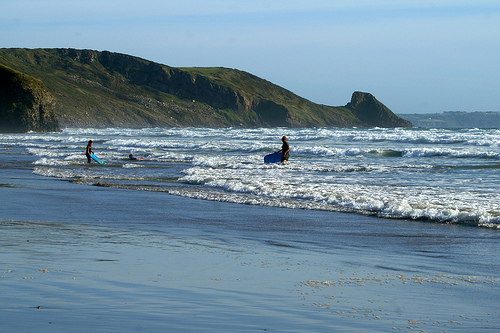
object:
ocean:
[1, 129, 500, 332]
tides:
[175, 165, 298, 201]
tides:
[351, 187, 495, 221]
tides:
[365, 147, 440, 161]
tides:
[364, 130, 449, 142]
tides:
[293, 127, 333, 139]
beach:
[2, 136, 499, 333]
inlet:
[0, 0, 500, 332]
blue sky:
[2, 0, 497, 112]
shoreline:
[0, 154, 500, 333]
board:
[264, 151, 288, 164]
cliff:
[0, 48, 413, 129]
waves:
[0, 127, 500, 231]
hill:
[0, 48, 426, 130]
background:
[0, 47, 499, 153]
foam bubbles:
[0, 127, 500, 230]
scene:
[0, 0, 499, 333]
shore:
[0, 147, 499, 333]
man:
[278, 136, 290, 165]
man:
[85, 140, 95, 163]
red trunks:
[136, 156, 144, 160]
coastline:
[0, 147, 499, 231]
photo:
[0, 0, 500, 332]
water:
[0, 128, 499, 332]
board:
[89, 152, 107, 166]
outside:
[0, 0, 500, 332]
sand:
[0, 157, 499, 333]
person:
[128, 154, 144, 161]